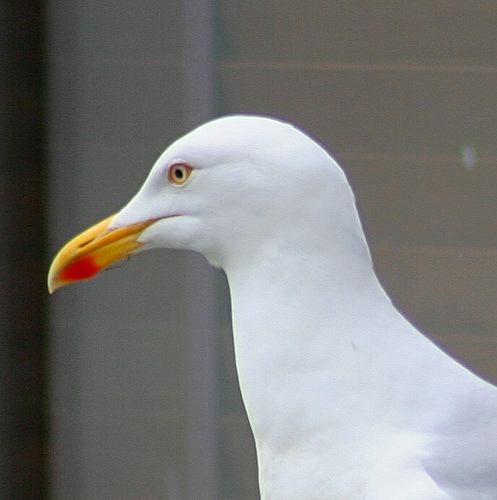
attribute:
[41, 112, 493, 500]
seagull — white, large, looking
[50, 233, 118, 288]
beak — orange, yellow, closed, curved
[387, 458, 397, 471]
feather — white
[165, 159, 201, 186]
eye — yellow, orange, green, open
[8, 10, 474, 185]
background — blurry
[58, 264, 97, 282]
spot — red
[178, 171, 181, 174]
pupil — large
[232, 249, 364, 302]
neck — white, long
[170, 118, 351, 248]
head — white